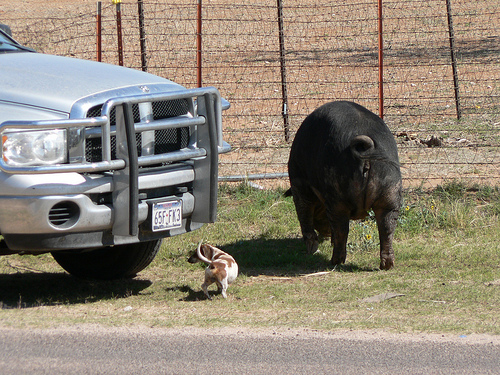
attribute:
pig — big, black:
[275, 97, 406, 277]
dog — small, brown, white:
[185, 236, 240, 303]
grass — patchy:
[0, 181, 497, 334]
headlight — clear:
[0, 125, 70, 170]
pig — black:
[284, 102, 402, 270]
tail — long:
[195, 240, 215, 268]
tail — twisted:
[348, 128, 385, 166]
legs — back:
[332, 212, 355, 269]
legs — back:
[375, 209, 396, 273]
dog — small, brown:
[185, 237, 249, 309]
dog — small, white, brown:
[181, 241, 239, 299]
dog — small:
[171, 239, 244, 301]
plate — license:
[145, 196, 186, 236]